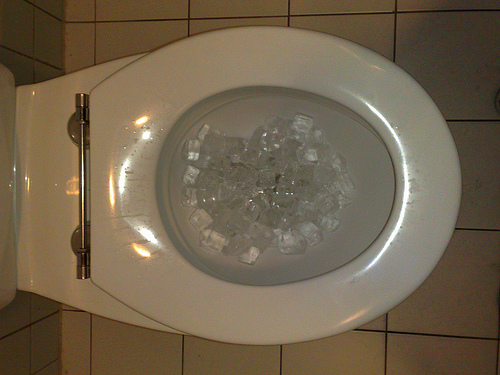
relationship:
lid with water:
[84, 24, 464, 346] [101, 126, 360, 251]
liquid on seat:
[102, 112, 157, 232] [85, 23, 463, 346]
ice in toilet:
[180, 113, 359, 264] [10, 25, 464, 347]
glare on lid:
[119, 214, 164, 259] [84, 24, 464, 346]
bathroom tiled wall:
[5, 3, 495, 372] [12, 311, 57, 371]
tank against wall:
[0, 66, 21, 311] [6, 306, 53, 370]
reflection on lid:
[376, 185, 418, 264] [84, 24, 464, 346]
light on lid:
[387, 223, 403, 249] [84, 24, 464, 346]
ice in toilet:
[252, 195, 302, 245] [5, 20, 463, 351]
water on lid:
[121, 161, 133, 180] [84, 24, 464, 346]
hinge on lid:
[73, 92, 90, 279] [84, 24, 464, 346]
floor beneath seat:
[409, 257, 489, 354] [85, 23, 463, 346]